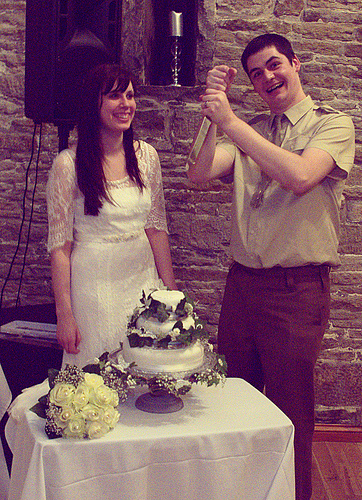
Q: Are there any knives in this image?
A: Yes, there is a knife.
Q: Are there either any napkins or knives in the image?
A: Yes, there is a knife.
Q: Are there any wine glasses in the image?
A: No, there are no wine glasses.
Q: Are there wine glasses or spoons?
A: No, there are no wine glasses or spoons.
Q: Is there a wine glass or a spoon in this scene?
A: No, there are no wine glasses or spoons.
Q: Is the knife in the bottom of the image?
A: No, the knife is in the top of the image.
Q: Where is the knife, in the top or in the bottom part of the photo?
A: The knife is in the top of the image.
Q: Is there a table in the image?
A: Yes, there is a table.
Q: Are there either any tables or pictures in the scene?
A: Yes, there is a table.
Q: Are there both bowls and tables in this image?
A: No, there is a table but no bowls.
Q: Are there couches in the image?
A: No, there are no couches.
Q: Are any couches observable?
A: No, there are no couches.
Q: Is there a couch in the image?
A: No, there are no couches.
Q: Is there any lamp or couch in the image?
A: No, there are no couches or lamps.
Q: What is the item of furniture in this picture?
A: The piece of furniture is a table.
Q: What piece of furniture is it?
A: The piece of furniture is a table.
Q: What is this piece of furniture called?
A: This is a table.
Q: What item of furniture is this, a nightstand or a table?
A: This is a table.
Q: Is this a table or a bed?
A: This is a table.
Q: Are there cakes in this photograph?
A: Yes, there is a cake.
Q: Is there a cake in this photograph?
A: Yes, there is a cake.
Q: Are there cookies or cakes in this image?
A: Yes, there is a cake.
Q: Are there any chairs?
A: No, there are no chairs.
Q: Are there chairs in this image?
A: No, there are no chairs.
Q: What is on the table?
A: The cake is on the table.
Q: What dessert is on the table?
A: The dessert is a cake.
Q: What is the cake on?
A: The cake is on the table.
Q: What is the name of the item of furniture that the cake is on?
A: The piece of furniture is a table.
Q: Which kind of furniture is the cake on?
A: The cake is on the table.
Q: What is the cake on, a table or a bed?
A: The cake is on a table.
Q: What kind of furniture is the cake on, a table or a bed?
A: The cake is on a table.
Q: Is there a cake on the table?
A: Yes, there is a cake on the table.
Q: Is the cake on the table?
A: Yes, the cake is on the table.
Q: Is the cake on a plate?
A: No, the cake is on the table.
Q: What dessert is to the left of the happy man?
A: The dessert is a cake.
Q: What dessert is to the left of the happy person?
A: The dessert is a cake.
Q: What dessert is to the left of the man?
A: The dessert is a cake.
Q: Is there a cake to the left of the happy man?
A: Yes, there is a cake to the left of the man.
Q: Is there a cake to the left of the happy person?
A: Yes, there is a cake to the left of the man.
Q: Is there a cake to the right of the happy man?
A: No, the cake is to the left of the man.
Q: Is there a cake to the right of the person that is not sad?
A: No, the cake is to the left of the man.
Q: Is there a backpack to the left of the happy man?
A: No, there is a cake to the left of the man.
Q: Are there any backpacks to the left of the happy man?
A: No, there is a cake to the left of the man.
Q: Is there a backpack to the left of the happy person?
A: No, there is a cake to the left of the man.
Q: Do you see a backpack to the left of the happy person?
A: No, there is a cake to the left of the man.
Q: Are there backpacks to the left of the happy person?
A: No, there is a cake to the left of the man.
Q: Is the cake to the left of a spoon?
A: No, the cake is to the left of the man.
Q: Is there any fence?
A: No, there are no fences.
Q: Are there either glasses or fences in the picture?
A: No, there are no fences or glasses.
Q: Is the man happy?
A: Yes, the man is happy.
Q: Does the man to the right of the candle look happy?
A: Yes, the man is happy.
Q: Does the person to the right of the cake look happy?
A: Yes, the man is happy.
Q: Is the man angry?
A: No, the man is happy.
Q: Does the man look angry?
A: No, the man is happy.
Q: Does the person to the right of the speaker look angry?
A: No, the man is happy.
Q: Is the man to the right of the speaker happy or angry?
A: The man is happy.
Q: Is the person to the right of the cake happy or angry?
A: The man is happy.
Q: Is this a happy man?
A: Yes, this is a happy man.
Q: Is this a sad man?
A: No, this is a happy man.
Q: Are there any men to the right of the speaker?
A: Yes, there is a man to the right of the speaker.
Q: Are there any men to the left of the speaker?
A: No, the man is to the right of the speaker.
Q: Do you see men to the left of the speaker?
A: No, the man is to the right of the speaker.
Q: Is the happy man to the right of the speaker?
A: Yes, the man is to the right of the speaker.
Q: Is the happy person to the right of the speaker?
A: Yes, the man is to the right of the speaker.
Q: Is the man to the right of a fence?
A: No, the man is to the right of the speaker.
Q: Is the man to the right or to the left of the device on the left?
A: The man is to the right of the speaker.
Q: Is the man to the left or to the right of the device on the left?
A: The man is to the right of the speaker.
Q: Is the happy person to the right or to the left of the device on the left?
A: The man is to the right of the speaker.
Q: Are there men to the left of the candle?
A: No, the man is to the right of the candle.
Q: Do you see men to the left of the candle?
A: No, the man is to the right of the candle.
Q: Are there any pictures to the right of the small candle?
A: No, there is a man to the right of the candle.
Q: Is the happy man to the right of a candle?
A: Yes, the man is to the right of a candle.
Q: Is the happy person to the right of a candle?
A: Yes, the man is to the right of a candle.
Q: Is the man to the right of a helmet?
A: No, the man is to the right of a candle.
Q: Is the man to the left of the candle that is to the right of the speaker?
A: No, the man is to the right of the candle.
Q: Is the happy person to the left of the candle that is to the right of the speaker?
A: No, the man is to the right of the candle.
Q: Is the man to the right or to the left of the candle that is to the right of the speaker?
A: The man is to the right of the candle.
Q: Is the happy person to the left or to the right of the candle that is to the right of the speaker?
A: The man is to the right of the candle.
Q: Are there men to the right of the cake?
A: Yes, there is a man to the right of the cake.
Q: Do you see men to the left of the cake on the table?
A: No, the man is to the right of the cake.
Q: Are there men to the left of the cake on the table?
A: No, the man is to the right of the cake.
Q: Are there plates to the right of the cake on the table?
A: No, there is a man to the right of the cake.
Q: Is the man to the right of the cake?
A: Yes, the man is to the right of the cake.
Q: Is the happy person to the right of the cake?
A: Yes, the man is to the right of the cake.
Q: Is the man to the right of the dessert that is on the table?
A: Yes, the man is to the right of the cake.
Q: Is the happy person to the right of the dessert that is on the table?
A: Yes, the man is to the right of the cake.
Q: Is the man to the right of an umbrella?
A: No, the man is to the right of the cake.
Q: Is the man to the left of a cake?
A: No, the man is to the right of a cake.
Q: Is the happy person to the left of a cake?
A: No, the man is to the right of a cake.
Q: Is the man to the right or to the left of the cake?
A: The man is to the right of the cake.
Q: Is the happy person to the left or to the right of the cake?
A: The man is to the right of the cake.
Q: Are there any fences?
A: No, there are no fences.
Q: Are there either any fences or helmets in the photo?
A: No, there are no fences or helmets.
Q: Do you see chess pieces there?
A: No, there are no chess pieces.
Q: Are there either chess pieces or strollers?
A: No, there are no chess pieces or strollers.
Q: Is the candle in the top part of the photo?
A: Yes, the candle is in the top of the image.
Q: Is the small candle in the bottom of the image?
A: No, the candle is in the top of the image.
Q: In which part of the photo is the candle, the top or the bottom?
A: The candle is in the top of the image.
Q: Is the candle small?
A: Yes, the candle is small.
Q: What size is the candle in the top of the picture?
A: The candle is small.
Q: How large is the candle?
A: The candle is small.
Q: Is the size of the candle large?
A: No, the candle is small.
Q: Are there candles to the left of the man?
A: Yes, there is a candle to the left of the man.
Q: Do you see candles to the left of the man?
A: Yes, there is a candle to the left of the man.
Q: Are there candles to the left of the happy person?
A: Yes, there is a candle to the left of the man.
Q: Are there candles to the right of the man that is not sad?
A: No, the candle is to the left of the man.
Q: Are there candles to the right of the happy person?
A: No, the candle is to the left of the man.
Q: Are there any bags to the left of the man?
A: No, there is a candle to the left of the man.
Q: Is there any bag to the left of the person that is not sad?
A: No, there is a candle to the left of the man.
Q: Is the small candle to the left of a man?
A: Yes, the candle is to the left of a man.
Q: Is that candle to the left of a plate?
A: No, the candle is to the left of a man.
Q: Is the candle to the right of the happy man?
A: No, the candle is to the left of the man.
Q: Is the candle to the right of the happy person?
A: No, the candle is to the left of the man.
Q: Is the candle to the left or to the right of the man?
A: The candle is to the left of the man.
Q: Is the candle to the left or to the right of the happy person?
A: The candle is to the left of the man.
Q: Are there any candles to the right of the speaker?
A: Yes, there is a candle to the right of the speaker.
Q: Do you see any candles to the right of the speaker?
A: Yes, there is a candle to the right of the speaker.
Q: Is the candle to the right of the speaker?
A: Yes, the candle is to the right of the speaker.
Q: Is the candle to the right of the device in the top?
A: Yes, the candle is to the right of the speaker.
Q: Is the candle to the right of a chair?
A: No, the candle is to the right of the speaker.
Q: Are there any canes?
A: No, there are no canes.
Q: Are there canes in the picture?
A: No, there are no canes.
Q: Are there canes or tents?
A: No, there are no canes or tents.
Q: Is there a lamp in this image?
A: No, there are no lamps.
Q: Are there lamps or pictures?
A: No, there are no lamps or pictures.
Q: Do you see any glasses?
A: No, there are no glasses.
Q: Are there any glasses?
A: No, there are no glasses.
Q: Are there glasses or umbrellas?
A: No, there are no glasses or umbrellas.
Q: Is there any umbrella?
A: No, there are no umbrellas.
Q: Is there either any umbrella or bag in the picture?
A: No, there are no umbrellas or bags.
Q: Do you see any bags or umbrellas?
A: No, there are no umbrellas or bags.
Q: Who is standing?
A: The people are standing.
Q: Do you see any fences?
A: No, there are no fences.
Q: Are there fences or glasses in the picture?
A: No, there are no fences or glasses.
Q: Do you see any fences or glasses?
A: No, there are no fences or glasses.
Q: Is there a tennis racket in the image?
A: No, there are no rackets.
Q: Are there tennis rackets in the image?
A: No, there are no tennis rackets.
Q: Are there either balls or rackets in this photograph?
A: No, there are no rackets or balls.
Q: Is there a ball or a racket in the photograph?
A: No, there are no rackets or balls.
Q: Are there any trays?
A: No, there are no trays.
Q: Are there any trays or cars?
A: No, there are no trays or cars.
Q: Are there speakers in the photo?
A: Yes, there is a speaker.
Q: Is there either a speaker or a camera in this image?
A: Yes, there is a speaker.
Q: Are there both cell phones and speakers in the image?
A: No, there is a speaker but no cell phones.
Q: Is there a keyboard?
A: No, there are no keyboards.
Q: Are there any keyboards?
A: No, there are no keyboards.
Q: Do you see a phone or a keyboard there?
A: No, there are no keyboards or phones.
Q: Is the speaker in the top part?
A: Yes, the speaker is in the top of the image.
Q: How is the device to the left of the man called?
A: The device is a speaker.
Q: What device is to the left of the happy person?
A: The device is a speaker.